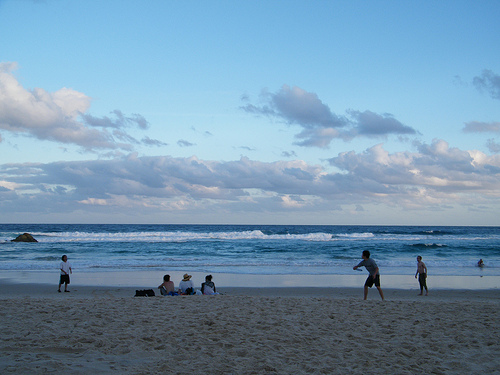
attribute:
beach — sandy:
[5, 256, 495, 373]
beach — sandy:
[43, 239, 430, 371]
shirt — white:
[59, 261, 72, 274]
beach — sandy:
[36, 219, 499, 370]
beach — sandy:
[44, 195, 498, 372]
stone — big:
[9, 227, 41, 247]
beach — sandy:
[4, 274, 491, 372]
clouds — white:
[2, 54, 496, 219]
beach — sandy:
[4, 232, 498, 373]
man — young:
[53, 250, 76, 291]